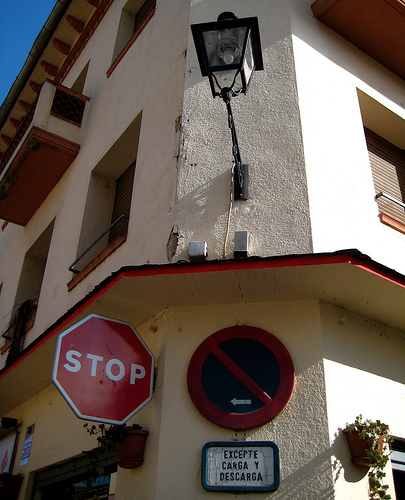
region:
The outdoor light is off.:
[183, 5, 276, 206]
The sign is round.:
[172, 313, 302, 433]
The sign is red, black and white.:
[181, 311, 300, 432]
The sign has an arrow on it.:
[178, 312, 297, 432]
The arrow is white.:
[225, 391, 256, 410]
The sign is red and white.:
[40, 306, 167, 431]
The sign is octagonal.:
[46, 308, 164, 445]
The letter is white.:
[62, 340, 84, 382]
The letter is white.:
[81, 345, 107, 383]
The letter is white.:
[123, 351, 149, 395]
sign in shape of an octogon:
[52, 312, 155, 425]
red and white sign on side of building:
[54, 312, 156, 425]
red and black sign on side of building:
[186, 323, 294, 432]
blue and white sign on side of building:
[203, 438, 279, 494]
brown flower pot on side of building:
[342, 413, 388, 493]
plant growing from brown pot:
[339, 416, 388, 498]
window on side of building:
[65, 105, 152, 295]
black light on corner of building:
[188, 9, 264, 111]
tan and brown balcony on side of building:
[0, 77, 88, 229]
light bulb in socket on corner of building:
[215, 40, 240, 64]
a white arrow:
[231, 397, 251, 407]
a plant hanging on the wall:
[341, 413, 390, 495]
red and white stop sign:
[54, 311, 155, 423]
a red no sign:
[185, 323, 293, 427]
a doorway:
[25, 448, 113, 497]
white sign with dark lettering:
[206, 446, 272, 485]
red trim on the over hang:
[0, 250, 404, 377]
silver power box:
[230, 231, 249, 254]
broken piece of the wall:
[164, 231, 180, 258]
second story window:
[74, 108, 140, 280]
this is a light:
[176, 4, 288, 113]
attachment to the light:
[198, 69, 253, 207]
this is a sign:
[36, 286, 175, 456]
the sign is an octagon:
[50, 273, 175, 459]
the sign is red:
[46, 297, 173, 441]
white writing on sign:
[37, 298, 166, 445]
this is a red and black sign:
[171, 320, 313, 447]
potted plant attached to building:
[337, 388, 403, 493]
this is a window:
[53, 129, 162, 284]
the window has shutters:
[50, 127, 156, 295]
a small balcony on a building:
[36, 67, 90, 180]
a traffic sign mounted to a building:
[60, 310, 171, 436]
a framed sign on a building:
[198, 437, 282, 492]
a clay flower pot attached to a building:
[335, 416, 396, 476]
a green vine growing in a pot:
[352, 406, 400, 499]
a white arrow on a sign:
[219, 387, 257, 414]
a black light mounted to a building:
[187, 16, 274, 206]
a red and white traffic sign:
[59, 321, 133, 422]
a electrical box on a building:
[172, 236, 211, 261]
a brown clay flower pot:
[118, 421, 147, 474]